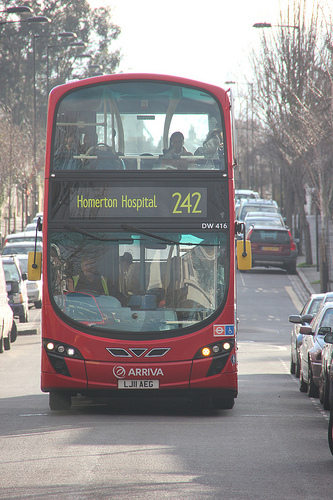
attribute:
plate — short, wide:
[105, 369, 197, 397]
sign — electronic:
[69, 187, 208, 216]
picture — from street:
[16, 406, 332, 494]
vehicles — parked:
[234, 179, 299, 272]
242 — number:
[169, 188, 203, 217]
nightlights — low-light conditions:
[195, 338, 234, 359]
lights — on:
[192, 340, 230, 359]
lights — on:
[40, 336, 83, 358]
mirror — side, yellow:
[237, 236, 251, 269]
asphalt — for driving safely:
[44, 407, 276, 492]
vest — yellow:
[97, 272, 110, 296]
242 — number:
[171, 190, 201, 213]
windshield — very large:
[41, 219, 235, 342]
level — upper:
[36, 72, 233, 177]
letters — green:
[75, 193, 160, 211]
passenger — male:
[62, 251, 121, 298]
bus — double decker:
[36, 68, 241, 414]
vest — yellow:
[66, 271, 109, 295]